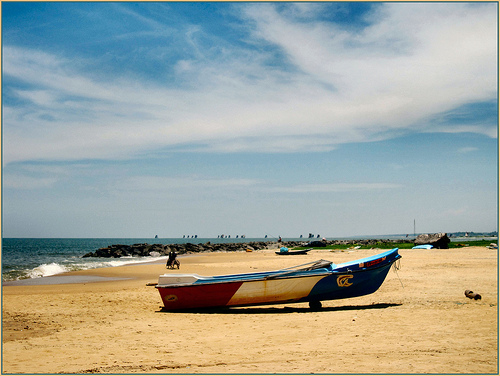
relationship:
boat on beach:
[143, 245, 405, 315] [4, 246, 496, 375]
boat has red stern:
[143, 245, 405, 315] [151, 272, 247, 314]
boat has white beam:
[143, 245, 405, 315] [222, 267, 344, 315]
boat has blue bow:
[143, 245, 405, 315] [306, 246, 403, 305]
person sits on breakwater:
[275, 234, 287, 245] [81, 237, 420, 260]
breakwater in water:
[81, 237, 420, 260] [4, 237, 499, 285]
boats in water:
[151, 232, 324, 240] [4, 237, 499, 285]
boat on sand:
[143, 245, 405, 315] [4, 246, 496, 375]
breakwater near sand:
[81, 237, 420, 260] [4, 246, 496, 375]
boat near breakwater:
[143, 245, 405, 315] [81, 237, 420, 260]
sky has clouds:
[4, 4, 498, 238] [3, 4, 499, 240]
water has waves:
[4, 237, 499, 285] [5, 250, 184, 283]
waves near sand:
[5, 250, 184, 283] [4, 246, 496, 375]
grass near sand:
[291, 238, 498, 251] [4, 246, 496, 375]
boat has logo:
[143, 245, 405, 315] [331, 270, 358, 290]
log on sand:
[464, 286, 481, 305] [4, 246, 496, 375]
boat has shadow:
[143, 245, 405, 315] [157, 300, 406, 317]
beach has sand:
[4, 246, 496, 375] [4, 246, 496, 375]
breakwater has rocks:
[81, 237, 420, 260] [80, 236, 417, 259]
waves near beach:
[5, 250, 184, 283] [4, 246, 496, 375]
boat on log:
[143, 245, 405, 315] [307, 298, 327, 314]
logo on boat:
[331, 270, 358, 290] [143, 245, 405, 315]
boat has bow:
[143, 245, 405, 315] [306, 246, 403, 305]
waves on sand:
[5, 250, 184, 283] [4, 246, 496, 375]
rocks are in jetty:
[83, 239, 200, 261] [4, 222, 275, 313]